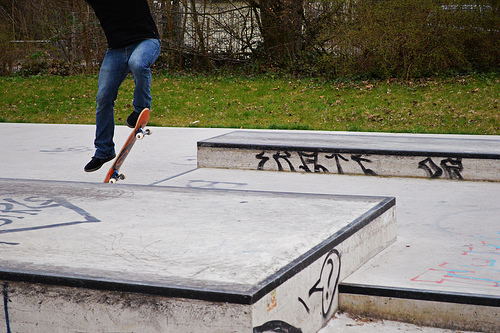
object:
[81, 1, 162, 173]
person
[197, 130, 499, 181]
platform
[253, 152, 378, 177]
graffiti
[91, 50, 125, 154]
leg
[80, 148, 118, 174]
shoe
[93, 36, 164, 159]
jeans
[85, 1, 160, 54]
shirt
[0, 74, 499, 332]
ground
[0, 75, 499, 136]
grass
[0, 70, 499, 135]
field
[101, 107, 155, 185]
skateboard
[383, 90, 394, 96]
leaves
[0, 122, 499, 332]
skatepark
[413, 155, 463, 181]
graffiti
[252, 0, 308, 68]
tree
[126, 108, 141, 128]
shoe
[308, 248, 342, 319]
graffiti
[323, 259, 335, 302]
question mark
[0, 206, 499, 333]
cement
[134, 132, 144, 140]
wheel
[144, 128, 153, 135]
wheel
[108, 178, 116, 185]
wheel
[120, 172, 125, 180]
wheel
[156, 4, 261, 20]
branch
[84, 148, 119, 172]
foot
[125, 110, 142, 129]
foot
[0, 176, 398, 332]
step